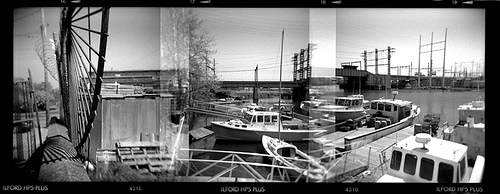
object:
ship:
[206, 103, 329, 142]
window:
[256, 115, 264, 123]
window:
[262, 114, 271, 123]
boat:
[453, 93, 485, 125]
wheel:
[55, 6, 111, 149]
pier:
[10, 65, 487, 184]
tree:
[155, 8, 220, 117]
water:
[359, 89, 484, 131]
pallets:
[113, 140, 176, 172]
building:
[85, 82, 191, 172]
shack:
[83, 82, 172, 162]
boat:
[260, 134, 332, 181]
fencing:
[170, 157, 327, 183]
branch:
[186, 31, 206, 59]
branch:
[185, 15, 203, 30]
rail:
[36, 116, 91, 183]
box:
[371, 120, 389, 131]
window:
[387, 150, 402, 172]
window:
[417, 156, 435, 181]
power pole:
[277, 30, 284, 110]